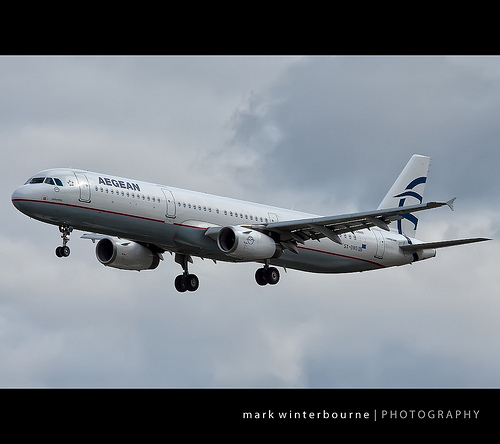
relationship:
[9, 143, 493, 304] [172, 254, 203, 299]
plane has landing gear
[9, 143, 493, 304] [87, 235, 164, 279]
plane has engine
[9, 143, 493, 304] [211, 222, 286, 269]
plane has engine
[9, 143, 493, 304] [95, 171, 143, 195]
plane has letters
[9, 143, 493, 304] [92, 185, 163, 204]
plane has windows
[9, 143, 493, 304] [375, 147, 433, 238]
plane has tail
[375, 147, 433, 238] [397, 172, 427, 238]
tail has symbol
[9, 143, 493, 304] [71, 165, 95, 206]
plane has door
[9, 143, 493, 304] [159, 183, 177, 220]
plane has door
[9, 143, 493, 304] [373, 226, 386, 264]
plane has door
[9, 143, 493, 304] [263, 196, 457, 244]
plane has wings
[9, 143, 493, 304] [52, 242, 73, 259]
plane has wheels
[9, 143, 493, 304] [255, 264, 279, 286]
plane has wheels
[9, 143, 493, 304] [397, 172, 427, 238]
plane has symbol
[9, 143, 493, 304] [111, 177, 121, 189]
plane has letter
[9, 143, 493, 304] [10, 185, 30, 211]
plane has nose